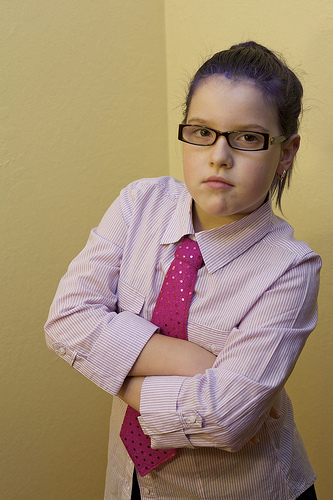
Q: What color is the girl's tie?
A: Pink.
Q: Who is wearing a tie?
A: Girl.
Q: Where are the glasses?
A: On the girl's face.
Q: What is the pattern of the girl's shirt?
A: Striped.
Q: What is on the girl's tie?
A: Polka dots.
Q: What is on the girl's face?
A: Glasses.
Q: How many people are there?
A: 1.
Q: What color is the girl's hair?
A: Brown.